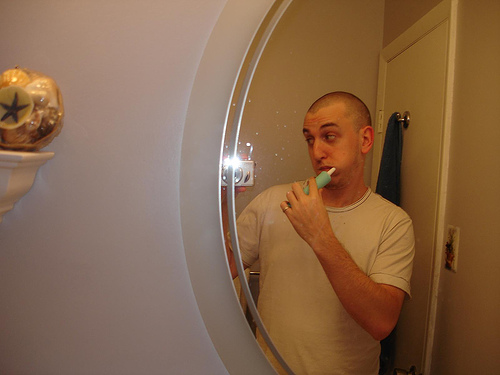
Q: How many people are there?
A: One.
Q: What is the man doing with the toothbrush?
A: Brushing his teeth.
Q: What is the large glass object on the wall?
A: A mirror.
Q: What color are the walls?
A: White.